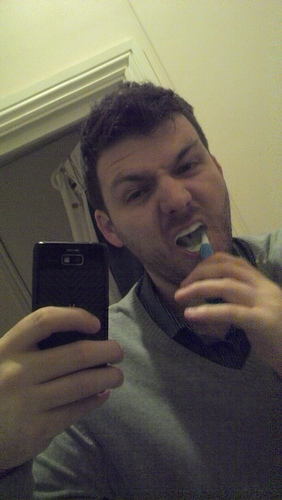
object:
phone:
[32, 241, 109, 371]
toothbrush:
[200, 231, 214, 260]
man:
[0, 79, 282, 500]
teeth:
[175, 220, 203, 242]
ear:
[94, 208, 123, 247]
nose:
[156, 166, 192, 216]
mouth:
[169, 213, 212, 258]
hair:
[79, 80, 208, 213]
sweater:
[0, 233, 282, 499]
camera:
[61, 253, 84, 266]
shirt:
[135, 238, 257, 371]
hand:
[0, 303, 124, 472]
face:
[94, 113, 232, 284]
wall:
[0, 0, 282, 234]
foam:
[186, 231, 209, 253]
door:
[0, 48, 162, 339]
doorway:
[0, 128, 82, 335]